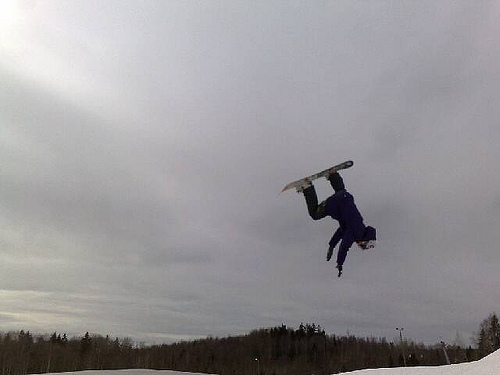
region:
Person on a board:
[277, 157, 357, 197]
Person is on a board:
[279, 152, 358, 194]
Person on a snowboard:
[278, 155, 358, 195]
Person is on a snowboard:
[274, 150, 359, 199]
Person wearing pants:
[302, 168, 347, 220]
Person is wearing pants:
[296, 169, 351, 224]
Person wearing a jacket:
[322, 189, 367, 264]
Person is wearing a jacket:
[322, 187, 362, 264]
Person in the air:
[270, 149, 398, 281]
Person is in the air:
[277, 149, 383, 279]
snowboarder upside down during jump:
[5, 0, 497, 343]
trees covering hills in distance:
[10, 310, 496, 370]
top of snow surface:
[60, 345, 495, 371]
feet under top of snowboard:
[275, 155, 355, 200]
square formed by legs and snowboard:
[305, 165, 345, 205]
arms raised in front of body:
[317, 210, 379, 280]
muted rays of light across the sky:
[11, 6, 211, 301]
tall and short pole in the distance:
[386, 320, 451, 366]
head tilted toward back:
[340, 217, 375, 252]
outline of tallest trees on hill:
[292, 320, 328, 336]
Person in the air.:
[248, 143, 414, 278]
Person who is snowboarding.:
[253, 150, 483, 289]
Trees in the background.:
[204, 303, 345, 372]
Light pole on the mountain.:
[368, 282, 427, 372]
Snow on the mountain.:
[411, 354, 488, 371]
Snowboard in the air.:
[231, 97, 358, 227]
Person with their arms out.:
[258, 132, 391, 322]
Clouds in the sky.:
[92, 199, 202, 355]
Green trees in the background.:
[246, 292, 352, 371]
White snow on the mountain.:
[372, 345, 472, 372]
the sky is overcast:
[91, 59, 224, 206]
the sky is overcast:
[112, 100, 220, 236]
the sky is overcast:
[120, 101, 239, 245]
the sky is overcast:
[105, 117, 210, 238]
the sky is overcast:
[95, 107, 235, 239]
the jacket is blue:
[331, 197, 378, 258]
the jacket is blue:
[317, 198, 361, 260]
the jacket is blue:
[327, 202, 367, 259]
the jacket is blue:
[339, 197, 381, 262]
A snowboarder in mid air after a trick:
[275, 152, 388, 289]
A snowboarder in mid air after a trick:
[276, 154, 383, 287]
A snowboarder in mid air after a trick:
[273, 150, 383, 286]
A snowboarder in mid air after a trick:
[273, 158, 388, 283]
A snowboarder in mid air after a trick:
[271, 153, 382, 282]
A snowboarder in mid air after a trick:
[270, 153, 389, 287]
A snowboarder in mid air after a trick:
[271, 155, 386, 299]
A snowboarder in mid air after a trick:
[267, 151, 385, 281]